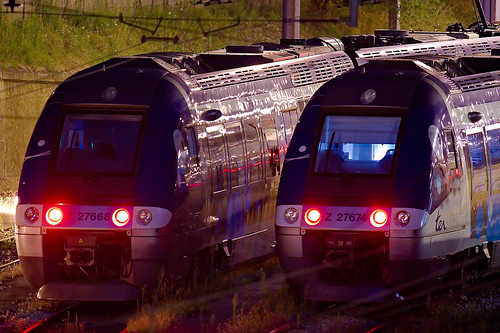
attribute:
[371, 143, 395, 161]
lights — on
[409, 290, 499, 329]
gravel — around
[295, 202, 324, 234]
light — main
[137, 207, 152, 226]
light — turned off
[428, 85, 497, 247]
side — blue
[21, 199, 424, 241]
lights — signaling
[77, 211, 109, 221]
numbers — black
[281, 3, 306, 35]
pole — gray, metal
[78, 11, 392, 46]
wires — electrical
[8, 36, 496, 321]
trains — electric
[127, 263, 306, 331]
grass — overgrown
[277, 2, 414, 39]
poles — electrical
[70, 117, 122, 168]
inside — dark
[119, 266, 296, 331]
weeds — overgrown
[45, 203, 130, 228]
train lights — on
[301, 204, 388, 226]
train lights — on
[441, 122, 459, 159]
window — side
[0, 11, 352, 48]
wire — electric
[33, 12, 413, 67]
wires — above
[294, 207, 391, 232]
lights — bright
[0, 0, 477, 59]
grass — high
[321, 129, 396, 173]
blue lights — inside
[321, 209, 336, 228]
letter — Z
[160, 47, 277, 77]
top — opened